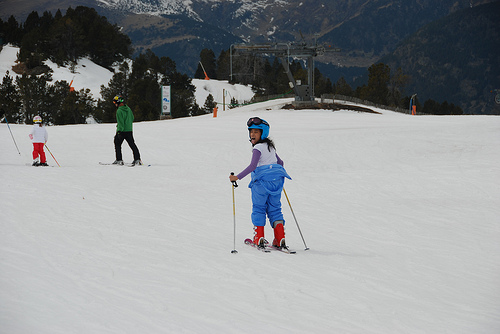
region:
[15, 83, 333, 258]
the people are skiing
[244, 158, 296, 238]
girl's pants are blue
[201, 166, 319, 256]
girl is holding ski poles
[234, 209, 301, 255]
girls's shoes are red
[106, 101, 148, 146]
person's shirt is green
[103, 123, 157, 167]
person's pants are black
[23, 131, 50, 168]
person's pants are red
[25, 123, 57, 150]
person's shirt is white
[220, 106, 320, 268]
person is looking back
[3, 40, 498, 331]
ground covered in snow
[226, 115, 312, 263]
A girl skiing in the snow.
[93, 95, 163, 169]
A man in green skiing in the snow.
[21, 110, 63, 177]
A child in red and white skiing in the snow.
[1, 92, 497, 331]
A white and snowy ski slope.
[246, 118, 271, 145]
A pair of goggles on a womans head.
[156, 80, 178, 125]
A sign in the snow.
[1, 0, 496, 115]
A mountain side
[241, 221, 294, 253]
Red ski shoes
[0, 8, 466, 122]
Trees on a hill in the background.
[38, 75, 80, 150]
An orange flag that is marking the ski slope.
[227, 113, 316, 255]
young female skier on snow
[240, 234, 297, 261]
skis on a young female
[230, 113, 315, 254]
young female skiing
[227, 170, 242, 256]
ski pole in a young skiers hand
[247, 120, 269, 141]
blue head gear on a young skier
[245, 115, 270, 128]
goggles on top of a young skiers head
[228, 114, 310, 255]
young girl holding two ski poles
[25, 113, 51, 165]
young skier dressed in red and white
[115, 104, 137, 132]
green jacket on a person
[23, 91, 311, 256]
three people on a field of snow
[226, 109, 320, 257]
kid wearing a hat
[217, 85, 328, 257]
kid wearing a pair of ski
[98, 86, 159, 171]
person wearing green jacket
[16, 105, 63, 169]
kid wearing red pant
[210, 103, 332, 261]
kid wearing blue pant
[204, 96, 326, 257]
kid holding two snow sticks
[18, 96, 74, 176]
kid holding snow stick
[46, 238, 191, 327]
a snowy field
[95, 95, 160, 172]
guy wearing a hat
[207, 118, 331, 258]
kid wearing a white vest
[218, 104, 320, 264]
girl skiing on the snow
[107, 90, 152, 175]
person wearing a green hoodie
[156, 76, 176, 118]
sign in the snow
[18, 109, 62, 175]
kid with red ski pants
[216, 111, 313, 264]
girl with red boots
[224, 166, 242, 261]
ski pole girl is holding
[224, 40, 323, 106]
ski lift on a crane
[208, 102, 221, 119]
orange pole in the ground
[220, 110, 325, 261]
girl with goggles on her head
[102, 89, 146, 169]
person with helmet on head